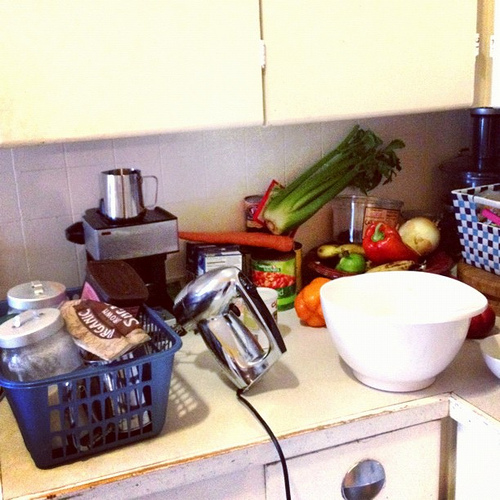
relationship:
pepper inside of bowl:
[362, 221, 424, 267] [304, 243, 456, 280]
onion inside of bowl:
[397, 215, 441, 255] [304, 243, 456, 280]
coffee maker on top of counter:
[64, 207, 182, 328] [0, 285, 499, 499]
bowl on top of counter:
[319, 269, 490, 395] [0, 285, 499, 499]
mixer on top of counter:
[171, 266, 288, 395] [0, 285, 499, 499]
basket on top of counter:
[0, 287, 183, 470] [0, 285, 499, 499]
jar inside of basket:
[1, 307, 87, 449] [0, 287, 183, 470]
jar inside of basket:
[6, 281, 70, 317] [0, 287, 183, 470]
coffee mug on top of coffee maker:
[100, 167, 160, 225] [64, 207, 182, 328]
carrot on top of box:
[176, 231, 295, 254] [195, 247, 244, 275]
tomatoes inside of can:
[252, 270, 294, 288] [247, 247, 296, 311]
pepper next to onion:
[362, 221, 424, 267] [397, 215, 441, 255]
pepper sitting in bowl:
[362, 221, 424, 267] [304, 243, 456, 280]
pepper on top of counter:
[294, 276, 331, 328] [0, 285, 499, 499]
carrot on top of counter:
[176, 231, 295, 254] [0, 285, 499, 499]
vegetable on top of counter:
[263, 123, 408, 235] [0, 285, 499, 499]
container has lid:
[79, 260, 150, 320] [85, 259, 150, 302]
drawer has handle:
[263, 419, 445, 500] [340, 456, 387, 498]